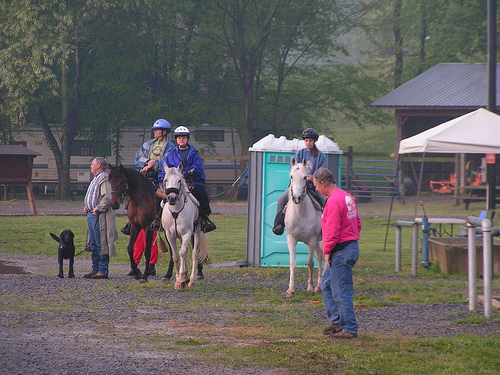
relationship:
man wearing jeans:
[310, 166, 364, 340] [317, 238, 362, 341]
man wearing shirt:
[310, 166, 364, 340] [314, 185, 365, 255]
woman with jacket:
[167, 123, 208, 204] [165, 143, 200, 175]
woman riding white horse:
[167, 123, 208, 204] [159, 160, 208, 292]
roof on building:
[355, 32, 499, 122] [394, 58, 499, 196]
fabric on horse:
[131, 227, 159, 264] [106, 163, 205, 284]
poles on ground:
[480, 220, 499, 319] [0, 195, 499, 370]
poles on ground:
[462, 218, 477, 310] [0, 195, 499, 370]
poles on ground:
[409, 222, 420, 282] [0, 195, 499, 370]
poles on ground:
[392, 218, 403, 273] [0, 195, 499, 370]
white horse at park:
[278, 153, 328, 300] [2, 1, 496, 372]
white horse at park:
[154, 160, 215, 290] [2, 1, 496, 372]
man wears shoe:
[310, 166, 364, 340] [331, 330, 355, 340]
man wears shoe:
[310, 166, 364, 340] [319, 320, 339, 333]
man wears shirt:
[311, 166, 364, 339] [318, 184, 361, 254]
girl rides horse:
[275, 125, 330, 290] [278, 126, 330, 286]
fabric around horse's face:
[163, 185, 184, 198] [161, 167, 181, 207]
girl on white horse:
[270, 127, 327, 237] [281, 157, 327, 300]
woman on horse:
[148, 123, 217, 234] [162, 160, 209, 287]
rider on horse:
[130, 117, 170, 232] [106, 167, 201, 278]